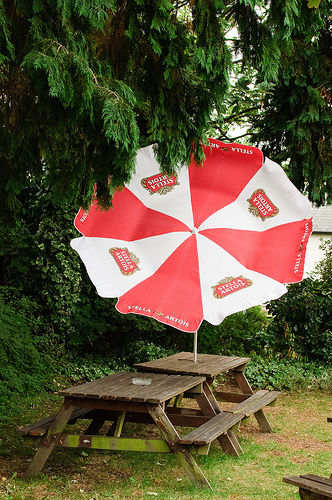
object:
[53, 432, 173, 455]
wood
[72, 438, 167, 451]
mold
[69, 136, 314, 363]
umbrella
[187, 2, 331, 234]
roof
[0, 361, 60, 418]
weeds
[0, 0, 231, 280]
tree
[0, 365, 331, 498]
land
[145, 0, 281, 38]
sky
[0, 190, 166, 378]
hillside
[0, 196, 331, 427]
plants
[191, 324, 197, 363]
pole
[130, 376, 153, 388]
ashtray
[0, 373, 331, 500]
grass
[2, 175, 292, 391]
bushes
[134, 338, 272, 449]
table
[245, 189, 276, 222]
beer manufacturer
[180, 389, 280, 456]
seats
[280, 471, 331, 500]
bench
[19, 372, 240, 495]
table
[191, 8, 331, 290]
buiding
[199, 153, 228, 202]
red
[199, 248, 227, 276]
white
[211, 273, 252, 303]
logo